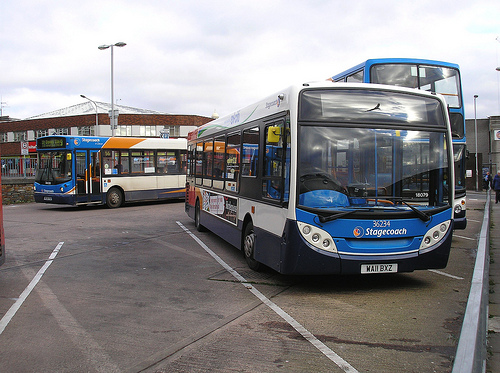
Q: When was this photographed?
A: Daytime.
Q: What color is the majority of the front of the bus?
A: Blue.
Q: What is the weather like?
A: Cloudy.